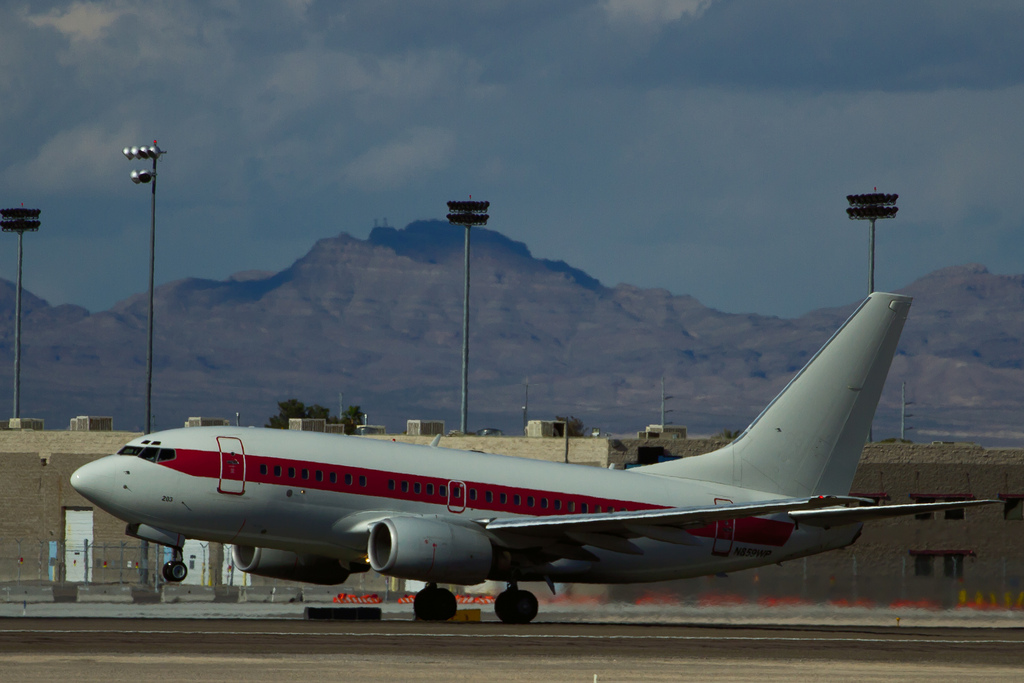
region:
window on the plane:
[244, 451, 276, 480]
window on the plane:
[292, 468, 318, 489]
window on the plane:
[589, 492, 619, 509]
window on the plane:
[520, 493, 559, 512]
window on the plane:
[434, 468, 482, 510]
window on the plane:
[418, 481, 448, 498]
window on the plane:
[326, 464, 350, 493]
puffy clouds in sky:
[94, 35, 402, 171]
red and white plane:
[117, 288, 914, 598]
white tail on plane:
[753, 294, 899, 503]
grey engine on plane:
[363, 511, 490, 600]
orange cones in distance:
[320, 572, 1011, 620]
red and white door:
[208, 430, 266, 511]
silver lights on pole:
[95, 127, 173, 412]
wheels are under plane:
[392, 557, 539, 628]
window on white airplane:
[251, 454, 267, 477]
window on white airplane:
[280, 460, 293, 479]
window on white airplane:
[324, 463, 335, 480]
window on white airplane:
[340, 466, 351, 485]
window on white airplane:
[354, 466, 364, 486]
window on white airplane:
[381, 473, 391, 494]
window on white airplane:
[408, 477, 422, 498]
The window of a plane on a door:
[221, 454, 235, 468]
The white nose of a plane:
[75, 468, 104, 491]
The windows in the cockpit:
[131, 444, 161, 458]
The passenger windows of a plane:
[274, 470, 348, 480]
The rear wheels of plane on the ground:
[498, 593, 538, 619]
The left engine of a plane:
[378, 520, 458, 571]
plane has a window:
[257, 458, 268, 471]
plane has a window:
[274, 457, 282, 476]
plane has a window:
[286, 463, 296, 480]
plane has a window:
[301, 463, 312, 480]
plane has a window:
[318, 466, 329, 483]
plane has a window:
[356, 467, 366, 484]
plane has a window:
[388, 475, 396, 489]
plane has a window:
[397, 475, 408, 489]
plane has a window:
[415, 479, 422, 492]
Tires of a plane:
[408, 581, 463, 623]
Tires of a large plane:
[408, 584, 463, 626]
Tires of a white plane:
[404, 578, 463, 626]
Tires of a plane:
[489, 584, 546, 629]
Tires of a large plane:
[480, 581, 547, 630]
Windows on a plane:
[287, 461, 351, 493]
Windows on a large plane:
[249, 448, 330, 496]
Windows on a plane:
[490, 487, 549, 516]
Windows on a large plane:
[496, 489, 567, 521]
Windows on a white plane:
[482, 484, 543, 513]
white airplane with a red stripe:
[69, 288, 1002, 621]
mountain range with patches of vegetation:
[2, 215, 1023, 450]